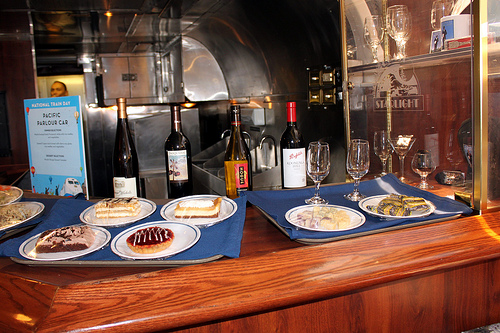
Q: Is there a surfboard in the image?
A: No, there are no surfboards.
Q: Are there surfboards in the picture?
A: No, there are no surfboards.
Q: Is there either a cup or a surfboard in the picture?
A: No, there are no surfboards or cups.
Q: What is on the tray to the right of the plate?
A: The glass is on the tray.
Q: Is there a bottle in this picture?
A: Yes, there is a bottle.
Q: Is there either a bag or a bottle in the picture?
A: Yes, there is a bottle.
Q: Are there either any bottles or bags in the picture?
A: Yes, there is a bottle.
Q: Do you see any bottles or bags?
A: Yes, there is a bottle.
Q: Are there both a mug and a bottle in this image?
A: No, there is a bottle but no mugs.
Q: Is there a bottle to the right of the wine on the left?
A: Yes, there is a bottle to the right of the wine.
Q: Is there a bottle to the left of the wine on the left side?
A: No, the bottle is to the right of the wine.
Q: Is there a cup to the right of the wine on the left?
A: No, there is a bottle to the right of the wine.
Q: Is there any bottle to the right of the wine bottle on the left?
A: Yes, there is a bottle to the right of the wine bottle.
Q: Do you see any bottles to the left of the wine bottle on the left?
A: No, the bottle is to the right of the wine bottle.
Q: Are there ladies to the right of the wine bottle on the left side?
A: No, there is a bottle to the right of the wine bottle.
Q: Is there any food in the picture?
A: Yes, there is food.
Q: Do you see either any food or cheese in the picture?
A: Yes, there is food.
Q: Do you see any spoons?
A: No, there are no spoons.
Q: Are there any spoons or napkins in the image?
A: No, there are no spoons or napkins.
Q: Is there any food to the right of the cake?
A: Yes, there is food to the right of the cake.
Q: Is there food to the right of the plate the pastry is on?
A: Yes, there is food to the right of the plate.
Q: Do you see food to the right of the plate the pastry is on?
A: Yes, there is food to the right of the plate.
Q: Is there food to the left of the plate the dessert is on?
A: No, the food is to the right of the plate.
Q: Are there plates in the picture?
A: Yes, there is a plate.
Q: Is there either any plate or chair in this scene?
A: Yes, there is a plate.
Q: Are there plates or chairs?
A: Yes, there is a plate.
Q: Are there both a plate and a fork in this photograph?
A: No, there is a plate but no forks.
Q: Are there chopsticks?
A: No, there are no chopsticks.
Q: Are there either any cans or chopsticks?
A: No, there are no chopsticks or cans.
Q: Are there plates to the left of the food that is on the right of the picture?
A: Yes, there is a plate to the left of the food.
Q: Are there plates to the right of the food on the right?
A: No, the plate is to the left of the food.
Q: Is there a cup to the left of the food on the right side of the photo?
A: No, there is a plate to the left of the food.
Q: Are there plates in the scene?
A: Yes, there is a plate.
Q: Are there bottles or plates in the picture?
A: Yes, there is a plate.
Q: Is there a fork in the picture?
A: No, there are no forks.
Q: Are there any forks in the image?
A: No, there are no forks.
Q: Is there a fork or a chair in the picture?
A: No, there are no forks or chairs.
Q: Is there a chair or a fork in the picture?
A: No, there are no forks or chairs.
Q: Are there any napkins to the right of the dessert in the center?
A: No, there is a plate to the right of the dessert.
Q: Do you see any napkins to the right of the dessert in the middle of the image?
A: No, there is a plate to the right of the dessert.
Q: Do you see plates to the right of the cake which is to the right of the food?
A: Yes, there is a plate to the right of the cake.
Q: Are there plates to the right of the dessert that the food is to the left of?
A: Yes, there is a plate to the right of the cake.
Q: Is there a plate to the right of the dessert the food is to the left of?
A: Yes, there is a plate to the right of the cake.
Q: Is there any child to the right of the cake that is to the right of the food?
A: No, there is a plate to the right of the cake.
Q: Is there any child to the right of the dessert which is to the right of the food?
A: No, there is a plate to the right of the cake.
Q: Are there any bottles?
A: Yes, there is a bottle.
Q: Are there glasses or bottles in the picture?
A: Yes, there is a bottle.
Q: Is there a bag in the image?
A: No, there are no bags.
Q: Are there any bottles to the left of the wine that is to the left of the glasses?
A: Yes, there is a bottle to the left of the wine.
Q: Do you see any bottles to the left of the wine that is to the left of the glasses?
A: Yes, there is a bottle to the left of the wine.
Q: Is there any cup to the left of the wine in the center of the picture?
A: No, there is a bottle to the left of the wine.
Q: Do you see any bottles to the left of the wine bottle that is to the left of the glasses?
A: Yes, there is a bottle to the left of the wine bottle.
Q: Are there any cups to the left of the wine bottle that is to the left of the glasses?
A: No, there is a bottle to the left of the wine bottle.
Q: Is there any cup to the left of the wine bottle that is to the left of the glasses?
A: No, there is a bottle to the left of the wine bottle.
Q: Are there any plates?
A: Yes, there is a plate.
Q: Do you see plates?
A: Yes, there is a plate.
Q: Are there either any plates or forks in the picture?
A: Yes, there is a plate.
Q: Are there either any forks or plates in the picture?
A: Yes, there is a plate.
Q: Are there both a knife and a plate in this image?
A: No, there is a plate but no knives.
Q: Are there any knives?
A: No, there are no knives.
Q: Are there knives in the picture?
A: No, there are no knives.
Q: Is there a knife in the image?
A: No, there are no knives.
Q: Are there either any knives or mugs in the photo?
A: No, there are no knives or mugs.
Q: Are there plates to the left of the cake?
A: Yes, there is a plate to the left of the cake.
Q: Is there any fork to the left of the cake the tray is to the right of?
A: No, there is a plate to the left of the cake.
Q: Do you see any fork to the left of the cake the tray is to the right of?
A: No, there is a plate to the left of the cake.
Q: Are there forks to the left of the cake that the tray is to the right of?
A: No, there is a plate to the left of the cake.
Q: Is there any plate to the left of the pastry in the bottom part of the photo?
A: Yes, there is a plate to the left of the pastry.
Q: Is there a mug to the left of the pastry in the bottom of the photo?
A: No, there is a plate to the left of the pastry.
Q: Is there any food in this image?
A: Yes, there is food.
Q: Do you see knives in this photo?
A: No, there are no knives.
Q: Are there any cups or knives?
A: No, there are no knives or cups.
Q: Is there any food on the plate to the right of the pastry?
A: Yes, there is food on the plate.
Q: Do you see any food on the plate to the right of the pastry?
A: Yes, there is food on the plate.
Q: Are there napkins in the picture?
A: No, there are no napkins.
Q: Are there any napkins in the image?
A: No, there are no napkins.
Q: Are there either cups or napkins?
A: No, there are no napkins or cups.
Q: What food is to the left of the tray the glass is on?
A: The food is a pastry.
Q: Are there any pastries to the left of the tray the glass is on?
A: Yes, there is a pastry to the left of the tray.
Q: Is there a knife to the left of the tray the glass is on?
A: No, there is a pastry to the left of the tray.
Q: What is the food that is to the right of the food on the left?
A: The food is a pastry.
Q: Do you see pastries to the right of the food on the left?
A: Yes, there is a pastry to the right of the food.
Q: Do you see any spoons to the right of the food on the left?
A: No, there is a pastry to the right of the food.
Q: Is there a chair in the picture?
A: No, there are no chairs.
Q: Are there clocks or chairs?
A: No, there are no chairs or clocks.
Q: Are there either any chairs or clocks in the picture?
A: No, there are no chairs or clocks.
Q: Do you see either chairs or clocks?
A: No, there are no chairs or clocks.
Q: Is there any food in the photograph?
A: Yes, there is food.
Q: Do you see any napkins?
A: No, there are no napkins.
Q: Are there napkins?
A: No, there are no napkins.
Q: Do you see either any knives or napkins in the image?
A: No, there are no napkins or knives.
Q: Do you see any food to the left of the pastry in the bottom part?
A: Yes, there is food to the left of the pastry.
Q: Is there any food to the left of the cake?
A: Yes, there is food to the left of the cake.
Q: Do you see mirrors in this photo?
A: No, there are no mirrors.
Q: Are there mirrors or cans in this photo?
A: No, there are no mirrors or cans.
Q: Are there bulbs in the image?
A: No, there are no bulbs.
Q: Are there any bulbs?
A: No, there are no bulbs.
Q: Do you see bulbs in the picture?
A: No, there are no bulbs.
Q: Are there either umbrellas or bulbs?
A: No, there are no bulbs or umbrellas.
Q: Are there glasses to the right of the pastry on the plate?
A: Yes, there are glasses to the right of the pastry.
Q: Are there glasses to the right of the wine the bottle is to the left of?
A: Yes, there are glasses to the right of the wine.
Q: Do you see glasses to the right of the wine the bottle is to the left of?
A: Yes, there are glasses to the right of the wine.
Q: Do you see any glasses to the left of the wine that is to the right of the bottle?
A: No, the glasses are to the right of the wine.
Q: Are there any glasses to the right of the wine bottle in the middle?
A: Yes, there are glasses to the right of the wine bottle.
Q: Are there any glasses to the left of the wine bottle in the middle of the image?
A: No, the glasses are to the right of the wine bottle.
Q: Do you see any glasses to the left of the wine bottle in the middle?
A: No, the glasses are to the right of the wine bottle.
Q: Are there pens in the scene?
A: No, there are no pens.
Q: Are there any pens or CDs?
A: No, there are no pens or cds.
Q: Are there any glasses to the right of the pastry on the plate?
A: Yes, there are glasses to the right of the pastry.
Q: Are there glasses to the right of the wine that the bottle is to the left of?
A: Yes, there are glasses to the right of the wine.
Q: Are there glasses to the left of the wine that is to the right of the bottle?
A: No, the glasses are to the right of the wine.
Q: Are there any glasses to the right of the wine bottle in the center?
A: Yes, there are glasses to the right of the wine bottle.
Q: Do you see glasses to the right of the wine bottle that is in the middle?
A: Yes, there are glasses to the right of the wine bottle.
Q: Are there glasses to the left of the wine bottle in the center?
A: No, the glasses are to the right of the wine bottle.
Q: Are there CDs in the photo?
A: No, there are no cds.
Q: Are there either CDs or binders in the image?
A: No, there are no CDs or binders.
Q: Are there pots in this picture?
A: No, there are no pots.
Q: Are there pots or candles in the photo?
A: No, there are no pots or candles.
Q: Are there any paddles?
A: No, there are no paddles.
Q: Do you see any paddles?
A: No, there are no paddles.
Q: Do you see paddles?
A: No, there are no paddles.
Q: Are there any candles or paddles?
A: No, there are no paddles or candles.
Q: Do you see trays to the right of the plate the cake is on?
A: Yes, there is a tray to the right of the plate.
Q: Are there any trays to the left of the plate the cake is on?
A: No, the tray is to the right of the plate.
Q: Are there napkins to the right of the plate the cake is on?
A: No, there is a tray to the right of the plate.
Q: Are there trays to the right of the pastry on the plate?
A: Yes, there is a tray to the right of the pastry.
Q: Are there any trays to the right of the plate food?
A: Yes, there is a tray to the right of the food.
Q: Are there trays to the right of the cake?
A: Yes, there is a tray to the right of the cake.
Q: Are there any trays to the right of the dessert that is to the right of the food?
A: Yes, there is a tray to the right of the cake.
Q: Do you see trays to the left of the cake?
A: No, the tray is to the right of the cake.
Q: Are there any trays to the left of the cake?
A: No, the tray is to the right of the cake.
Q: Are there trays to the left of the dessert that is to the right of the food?
A: No, the tray is to the right of the cake.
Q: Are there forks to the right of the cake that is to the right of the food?
A: No, there is a tray to the right of the cake.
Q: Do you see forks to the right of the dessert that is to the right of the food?
A: No, there is a tray to the right of the cake.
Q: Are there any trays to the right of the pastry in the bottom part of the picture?
A: Yes, there is a tray to the right of the pastry.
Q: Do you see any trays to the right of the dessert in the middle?
A: Yes, there is a tray to the right of the dessert.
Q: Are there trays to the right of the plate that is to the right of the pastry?
A: Yes, there is a tray to the right of the plate.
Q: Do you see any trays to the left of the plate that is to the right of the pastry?
A: No, the tray is to the right of the plate.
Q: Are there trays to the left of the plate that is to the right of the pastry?
A: No, the tray is to the right of the plate.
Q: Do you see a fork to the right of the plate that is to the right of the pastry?
A: No, there is a tray to the right of the plate.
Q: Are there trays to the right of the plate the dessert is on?
A: Yes, there is a tray to the right of the plate.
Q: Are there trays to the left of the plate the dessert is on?
A: No, the tray is to the right of the plate.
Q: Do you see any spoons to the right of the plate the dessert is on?
A: No, there is a tray to the right of the plate.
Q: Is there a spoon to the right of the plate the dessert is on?
A: No, there is a tray to the right of the plate.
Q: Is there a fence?
A: No, there are no fences.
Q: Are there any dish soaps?
A: No, there are no dish soaps.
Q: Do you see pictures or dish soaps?
A: No, there are no dish soaps or pictures.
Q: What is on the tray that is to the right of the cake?
A: The glass is on the tray.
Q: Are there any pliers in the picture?
A: No, there are no pliers.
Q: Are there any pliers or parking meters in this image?
A: No, there are no pliers or parking meters.